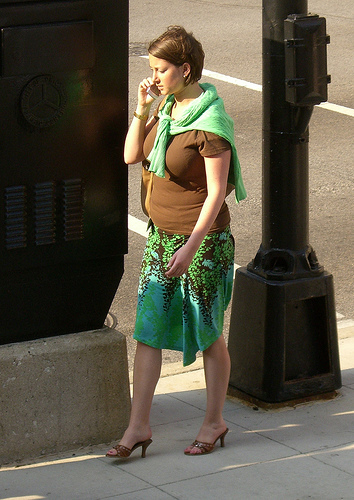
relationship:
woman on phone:
[103, 25, 236, 463] [142, 74, 162, 99]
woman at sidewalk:
[103, 25, 236, 463] [28, 434, 165, 494]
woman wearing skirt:
[103, 25, 236, 463] [126, 224, 245, 355]